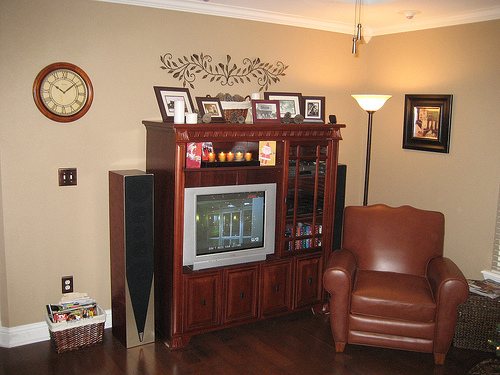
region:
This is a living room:
[7, 0, 498, 371]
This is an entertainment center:
[140, 113, 354, 339]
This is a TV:
[175, 179, 285, 274]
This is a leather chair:
[321, 195, 468, 372]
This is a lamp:
[350, 88, 391, 222]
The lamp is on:
[345, 80, 390, 214]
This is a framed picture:
[387, 88, 467, 165]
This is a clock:
[24, 56, 100, 127]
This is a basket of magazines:
[42, 295, 115, 357]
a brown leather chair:
[320, 197, 468, 353]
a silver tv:
[179, 176, 290, 277]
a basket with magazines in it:
[42, 283, 106, 359]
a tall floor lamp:
[350, 82, 392, 209]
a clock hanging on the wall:
[30, 52, 107, 131]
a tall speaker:
[115, 160, 163, 374]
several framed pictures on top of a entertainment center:
[150, 91, 330, 126]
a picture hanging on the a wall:
[393, 75, 460, 165]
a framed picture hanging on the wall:
[395, 81, 463, 161]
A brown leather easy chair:
[322, 204, 469, 361]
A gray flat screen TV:
[181, 182, 277, 271]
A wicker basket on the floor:
[41, 302, 108, 351]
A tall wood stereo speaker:
[108, 167, 158, 351]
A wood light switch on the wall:
[57, 167, 77, 185]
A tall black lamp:
[349, 93, 392, 203]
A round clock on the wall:
[30, 62, 94, 125]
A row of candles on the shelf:
[201, 149, 256, 165]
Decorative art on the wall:
[156, 49, 288, 92]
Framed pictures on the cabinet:
[149, 85, 327, 122]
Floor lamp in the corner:
[353, 91, 390, 201]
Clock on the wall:
[33, 60, 93, 125]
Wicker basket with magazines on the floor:
[48, 296, 107, 352]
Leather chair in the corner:
[323, 202, 467, 357]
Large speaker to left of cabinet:
[106, 168, 155, 350]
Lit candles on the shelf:
[202, 147, 256, 169]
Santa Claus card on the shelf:
[257, 137, 278, 166]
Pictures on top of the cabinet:
[152, 81, 327, 122]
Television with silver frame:
[181, 181, 278, 271]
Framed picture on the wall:
[401, 90, 456, 157]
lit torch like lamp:
[335, 69, 393, 224]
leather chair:
[315, 185, 462, 368]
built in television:
[170, 180, 280, 283]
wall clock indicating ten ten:
[28, 55, 100, 140]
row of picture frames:
[140, 79, 347, 146]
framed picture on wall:
[392, 78, 463, 177]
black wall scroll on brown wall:
[133, 26, 314, 104]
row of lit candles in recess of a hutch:
[189, 146, 264, 175]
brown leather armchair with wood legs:
[320, 202, 472, 369]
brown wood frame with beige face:
[28, 59, 93, 124]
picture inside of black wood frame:
[398, 91, 453, 154]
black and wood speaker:
[106, 165, 156, 349]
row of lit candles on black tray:
[201, 150, 258, 166]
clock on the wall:
[45, 56, 92, 130]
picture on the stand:
[164, 85, 204, 123]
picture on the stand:
[185, 78, 223, 125]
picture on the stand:
[248, 79, 275, 121]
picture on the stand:
[272, 92, 286, 106]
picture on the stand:
[304, 86, 325, 136]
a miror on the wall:
[402, 95, 452, 157]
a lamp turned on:
[335, 56, 420, 223]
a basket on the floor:
[37, 272, 131, 364]